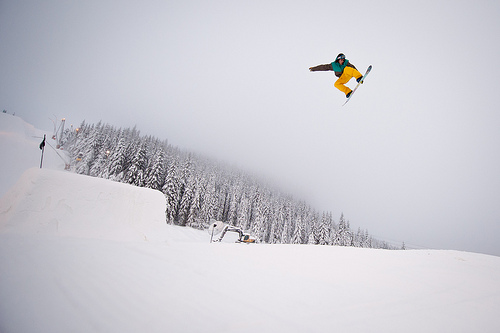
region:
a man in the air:
[288, 47, 387, 118]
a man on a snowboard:
[298, 48, 373, 141]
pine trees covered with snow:
[65, 126, 405, 243]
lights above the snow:
[47, 113, 83, 150]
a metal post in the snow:
[30, 131, 50, 167]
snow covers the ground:
[65, 241, 405, 327]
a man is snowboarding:
[302, 50, 373, 106]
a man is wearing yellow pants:
[302, 53, 377, 104]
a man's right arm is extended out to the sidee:
[300, 50, 375, 105]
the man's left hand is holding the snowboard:
[301, 53, 376, 108]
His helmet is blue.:
[328, 39, 360, 63]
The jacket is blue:
[310, 63, 365, 76]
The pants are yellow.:
[330, 62, 365, 99]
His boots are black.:
[338, 67, 368, 99]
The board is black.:
[333, 63, 380, 108]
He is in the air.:
[300, 38, 392, 90]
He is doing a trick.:
[307, 41, 382, 98]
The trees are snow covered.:
[40, 107, 367, 259]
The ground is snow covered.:
[21, 205, 493, 332]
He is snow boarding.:
[243, 43, 423, 120]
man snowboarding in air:
[290, 31, 382, 107]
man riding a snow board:
[308, 46, 385, 104]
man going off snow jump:
[0, 25, 420, 292]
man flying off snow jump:
[0, 14, 475, 305]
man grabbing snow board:
[286, 40, 393, 114]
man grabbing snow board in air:
[302, 48, 377, 129]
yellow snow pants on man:
[332, 63, 363, 100]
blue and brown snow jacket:
[329, 62, 354, 73]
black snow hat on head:
[337, 54, 348, 61]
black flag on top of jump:
[31, 128, 51, 177]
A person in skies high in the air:
[308, 51, 374, 103]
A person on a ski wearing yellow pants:
[308, 52, 370, 99]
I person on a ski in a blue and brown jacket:
[308, 52, 372, 98]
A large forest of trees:
[60, 119, 395, 249]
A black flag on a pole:
[37, 134, 47, 168]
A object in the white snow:
[207, 223, 258, 243]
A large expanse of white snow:
[3, 112, 498, 331]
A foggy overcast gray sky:
[0, 2, 499, 250]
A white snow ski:
[344, 62, 372, 104]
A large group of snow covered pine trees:
[70, 122, 405, 249]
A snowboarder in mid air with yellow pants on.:
[306, 53, 362, 100]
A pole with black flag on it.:
[39, 132, 46, 168]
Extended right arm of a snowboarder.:
[310, 63, 335, 74]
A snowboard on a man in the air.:
[340, 64, 375, 106]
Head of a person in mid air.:
[337, 52, 344, 66]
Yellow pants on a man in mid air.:
[332, 65, 362, 96]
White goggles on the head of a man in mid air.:
[334, 51, 345, 61]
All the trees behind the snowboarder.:
[56, 118, 402, 251]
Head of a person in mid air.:
[336, 51, 349, 64]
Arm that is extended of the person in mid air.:
[309, 61, 336, 72]